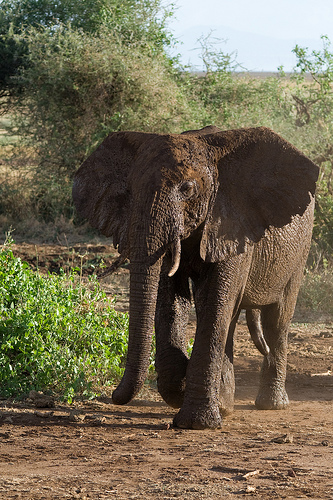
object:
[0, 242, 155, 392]
bush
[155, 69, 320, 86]
hills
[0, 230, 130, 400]
plant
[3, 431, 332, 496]
ground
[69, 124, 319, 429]
elephant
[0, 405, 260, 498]
sand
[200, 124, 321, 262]
ears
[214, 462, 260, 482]
stick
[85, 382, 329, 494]
mud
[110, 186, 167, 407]
trunk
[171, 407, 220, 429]
paw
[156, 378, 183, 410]
paw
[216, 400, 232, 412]
paw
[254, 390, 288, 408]
paw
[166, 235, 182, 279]
tusk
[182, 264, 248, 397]
leg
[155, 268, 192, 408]
leg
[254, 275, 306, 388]
leg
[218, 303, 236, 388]
leg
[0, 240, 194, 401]
vegetation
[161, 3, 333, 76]
cloud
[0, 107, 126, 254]
grass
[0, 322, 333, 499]
brown mud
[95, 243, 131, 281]
tusks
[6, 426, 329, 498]
surface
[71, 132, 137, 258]
ear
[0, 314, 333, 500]
dirt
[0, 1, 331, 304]
forest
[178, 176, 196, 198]
eye